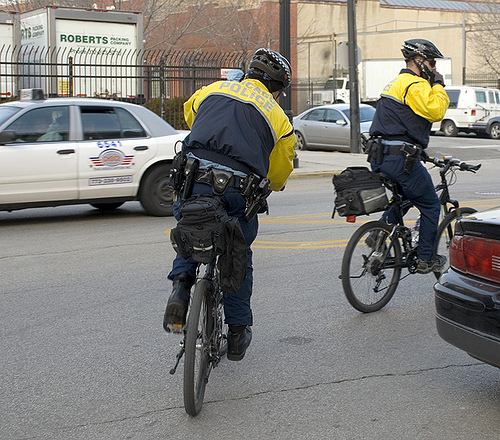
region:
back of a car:
[466, 291, 476, 308]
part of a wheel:
[184, 340, 194, 354]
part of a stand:
[168, 370, 178, 381]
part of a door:
[71, 165, 88, 194]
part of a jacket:
[242, 166, 259, 181]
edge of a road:
[302, 353, 321, 395]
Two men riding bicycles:
[151, 33, 487, 415]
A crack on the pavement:
[58, 356, 487, 431]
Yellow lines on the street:
[247, 199, 497, 252]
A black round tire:
[137, 157, 185, 217]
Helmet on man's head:
[388, 29, 446, 84]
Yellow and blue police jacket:
[173, 73, 300, 196]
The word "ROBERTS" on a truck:
[54, 29, 110, 46]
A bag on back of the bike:
[163, 187, 253, 299]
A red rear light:
[441, 224, 498, 288]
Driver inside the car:
[17, 105, 65, 147]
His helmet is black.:
[243, 41, 293, 83]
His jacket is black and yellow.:
[157, 69, 312, 199]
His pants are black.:
[153, 193, 285, 356]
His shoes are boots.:
[146, 281, 263, 380]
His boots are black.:
[137, 280, 265, 374]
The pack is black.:
[326, 163, 386, 233]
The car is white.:
[0, 88, 213, 212]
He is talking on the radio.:
[390, 40, 456, 101]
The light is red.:
[445, 230, 498, 277]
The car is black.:
[415, 210, 495, 347]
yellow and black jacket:
[183, 79, 296, 188]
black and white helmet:
[256, 45, 293, 86]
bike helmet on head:
[403, 38, 443, 60]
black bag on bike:
[170, 205, 232, 258]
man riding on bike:
[165, 48, 290, 416]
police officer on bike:
[338, 37, 480, 314]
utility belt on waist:
[171, 146, 270, 218]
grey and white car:
[3, 89, 188, 219]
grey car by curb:
[295, 103, 376, 150]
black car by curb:
[435, 204, 497, 372]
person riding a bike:
[331, 24, 463, 321]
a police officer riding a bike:
[138, 36, 310, 427]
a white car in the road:
[3, 79, 198, 223]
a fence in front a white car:
[6, 33, 186, 225]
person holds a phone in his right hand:
[367, 17, 460, 160]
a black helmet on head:
[382, 28, 452, 81]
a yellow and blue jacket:
[170, 73, 302, 201]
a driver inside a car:
[7, 101, 73, 171]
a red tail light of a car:
[425, 210, 499, 383]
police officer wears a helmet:
[185, 36, 320, 171]